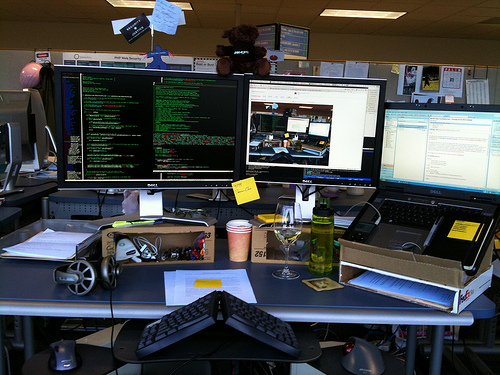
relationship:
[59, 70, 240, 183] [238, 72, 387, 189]
code on computer screen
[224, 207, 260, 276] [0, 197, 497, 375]
cup on desk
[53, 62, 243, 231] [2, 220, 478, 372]
computer on table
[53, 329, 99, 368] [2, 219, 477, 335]
mouse on table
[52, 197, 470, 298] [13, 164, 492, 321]
items on desk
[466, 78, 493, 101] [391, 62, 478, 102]
paper on board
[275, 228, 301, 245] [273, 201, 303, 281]
liquid in glass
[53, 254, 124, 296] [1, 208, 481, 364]
head phones on top of table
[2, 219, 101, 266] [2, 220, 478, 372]
paper on top of table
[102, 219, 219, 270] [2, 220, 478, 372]
stand on top of table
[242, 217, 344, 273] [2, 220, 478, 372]
stand on top of table